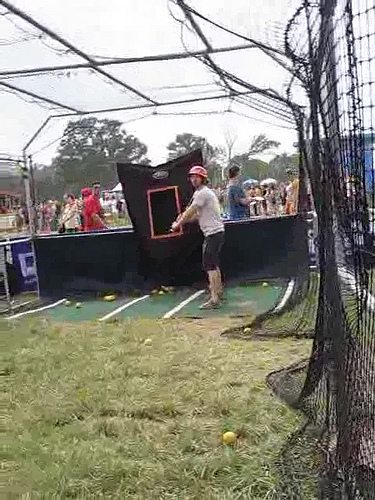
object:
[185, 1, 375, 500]
mesh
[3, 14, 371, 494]
pen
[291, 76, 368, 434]
side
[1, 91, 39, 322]
side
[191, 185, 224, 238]
shirt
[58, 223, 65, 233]
purse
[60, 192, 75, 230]
woman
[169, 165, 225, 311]
man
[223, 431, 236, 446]
ball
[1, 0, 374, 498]
enclosure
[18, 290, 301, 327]
ground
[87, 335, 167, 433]
grass